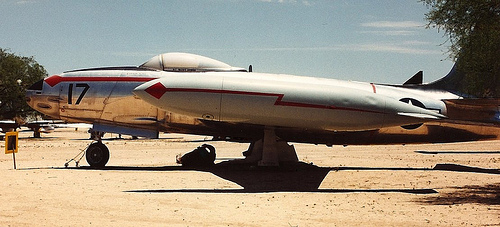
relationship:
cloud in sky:
[359, 20, 445, 28] [2, 3, 462, 91]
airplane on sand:
[22, 13, 499, 167] [0, 134, 499, 224]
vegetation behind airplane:
[418, 0, 498, 63] [22, 13, 499, 167]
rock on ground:
[305, 196, 321, 207] [2, 127, 494, 225]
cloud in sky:
[362, 18, 452, 35] [2, 0, 466, 79]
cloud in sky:
[359, 20, 445, 28] [2, 0, 466, 79]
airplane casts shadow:
[22, 13, 499, 167] [124, 157, 436, 202]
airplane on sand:
[19, 40, 494, 175] [2, 118, 498, 224]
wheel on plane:
[80, 139, 110, 164] [12, 48, 494, 190]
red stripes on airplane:
[45, 75, 379, 118] [22, 13, 499, 167]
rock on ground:
[170, 205, 180, 215] [2, 127, 494, 225]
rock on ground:
[173, 209, 180, 212] [2, 127, 494, 225]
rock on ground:
[173, 209, 180, 212] [357, 174, 440, 209]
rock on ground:
[311, 198, 318, 209] [2, 127, 494, 225]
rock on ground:
[36, 156, 46, 162] [2, 127, 494, 225]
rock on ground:
[173, 209, 180, 212] [5, 121, 498, 221]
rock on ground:
[425, 174, 434, 187] [5, 121, 498, 221]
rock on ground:
[422, 216, 432, 223] [5, 121, 498, 221]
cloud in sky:
[359, 20, 445, 28] [0, 2, 496, 89]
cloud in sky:
[359, 20, 445, 28] [19, 7, 448, 46]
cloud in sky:
[359, 20, 445, 28] [90, 11, 376, 68]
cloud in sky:
[359, 20, 445, 28] [263, 25, 418, 45]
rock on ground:
[173, 209, 180, 212] [155, 167, 245, 224]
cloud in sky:
[359, 20, 445, 28] [5, 1, 500, 133]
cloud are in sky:
[359, 20, 445, 28] [270, 11, 355, 61]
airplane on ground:
[22, 13, 499, 167] [14, 162, 482, 222]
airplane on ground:
[22, 13, 499, 167] [2, 127, 494, 225]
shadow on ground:
[25, 160, 497, 194] [2, 127, 494, 225]